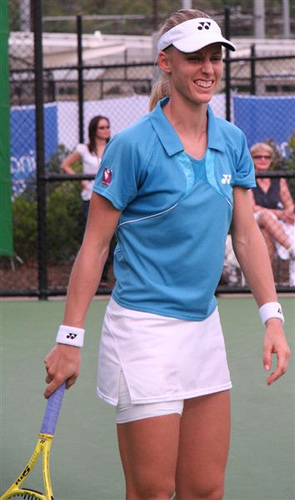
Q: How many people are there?
A: Three.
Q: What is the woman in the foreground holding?
A: A tennis racket.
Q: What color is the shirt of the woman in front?
A: Blue.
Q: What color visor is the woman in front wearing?
A: White.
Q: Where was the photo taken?
A: A tennis court.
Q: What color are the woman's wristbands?
A: White.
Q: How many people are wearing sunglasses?
A: Two.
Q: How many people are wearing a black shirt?
A: One.